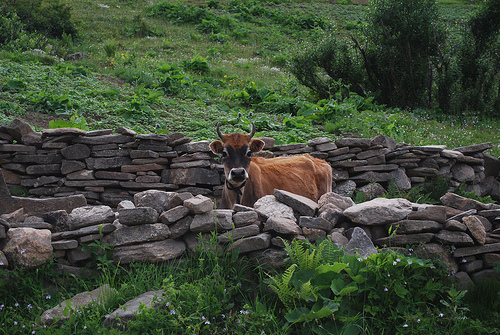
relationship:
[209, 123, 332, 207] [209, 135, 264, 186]
cow with face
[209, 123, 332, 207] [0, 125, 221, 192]
cow by wall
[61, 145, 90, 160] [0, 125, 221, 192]
rocks make a wall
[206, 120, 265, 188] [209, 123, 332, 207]
head of cow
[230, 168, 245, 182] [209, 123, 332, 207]
nose of cow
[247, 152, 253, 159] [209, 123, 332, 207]
eye of cow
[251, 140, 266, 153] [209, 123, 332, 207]
ear of cow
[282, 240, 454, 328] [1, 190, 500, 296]
shrub in front of wall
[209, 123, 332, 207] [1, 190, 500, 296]
cow looking over wall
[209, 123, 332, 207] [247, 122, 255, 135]
cow has horns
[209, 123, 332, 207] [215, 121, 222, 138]
cow has horns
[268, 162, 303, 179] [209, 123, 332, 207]
brown standing cow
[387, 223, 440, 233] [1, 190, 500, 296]
stone built wall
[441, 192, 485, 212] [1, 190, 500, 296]
stone built wall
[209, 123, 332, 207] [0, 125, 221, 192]
cow standing by wall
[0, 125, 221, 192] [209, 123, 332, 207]
wall behind cow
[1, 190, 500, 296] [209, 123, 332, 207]
wall in front of cow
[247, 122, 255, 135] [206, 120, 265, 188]
horns attached to head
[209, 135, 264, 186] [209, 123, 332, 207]
face of cow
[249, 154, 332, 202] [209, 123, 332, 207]
body of cow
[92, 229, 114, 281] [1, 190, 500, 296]
plant in front of wall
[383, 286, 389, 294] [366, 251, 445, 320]
flower attached to plant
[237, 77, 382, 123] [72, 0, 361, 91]
plants attached to hill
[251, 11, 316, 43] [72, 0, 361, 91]
grass on hill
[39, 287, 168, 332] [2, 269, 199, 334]
stones in grass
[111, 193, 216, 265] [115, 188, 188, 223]
stacked of stones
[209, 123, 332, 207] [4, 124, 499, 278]
cow in stone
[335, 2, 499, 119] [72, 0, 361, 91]
trees at bottom hill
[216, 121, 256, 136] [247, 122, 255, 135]
two curved horns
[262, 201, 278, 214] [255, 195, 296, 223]
bright colored rock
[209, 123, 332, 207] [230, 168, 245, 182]
cows black nose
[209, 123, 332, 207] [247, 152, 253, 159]
cow brown eye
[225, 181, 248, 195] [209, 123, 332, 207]
rope around cow